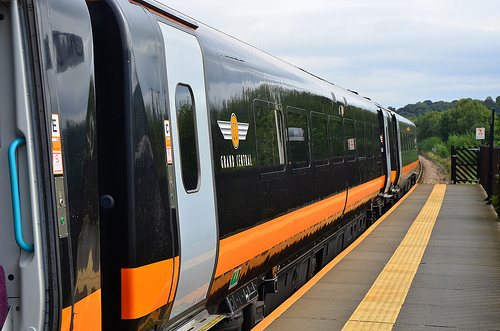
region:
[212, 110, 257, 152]
Orange circle with silver wings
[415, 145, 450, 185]
Dirt next to the train track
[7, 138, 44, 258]
Long blue door handle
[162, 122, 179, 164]
Sign next to the window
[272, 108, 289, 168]
Window on the side of the train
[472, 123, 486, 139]
White sign on the platform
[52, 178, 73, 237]
Silver and green buttons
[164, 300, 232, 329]
Silver step to the door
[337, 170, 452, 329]
Yellow stripe on the pavement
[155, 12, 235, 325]
Tall silver door of the train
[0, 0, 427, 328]
Train is sitting on tracks.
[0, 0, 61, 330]
Train door is open.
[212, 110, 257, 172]
Train logo is orange and white.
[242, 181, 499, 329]
Passenger loading area is concrete.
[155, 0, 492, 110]
Sky is lightly cloudy.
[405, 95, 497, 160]
Lush wooded area.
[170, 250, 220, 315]
Reflection from passenger loading area.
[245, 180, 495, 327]
Passenger loading area.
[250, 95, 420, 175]
Row of dark windows.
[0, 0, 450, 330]
Train has orange stripe.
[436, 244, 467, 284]
part of a floor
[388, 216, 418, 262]
part of a floor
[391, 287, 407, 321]
edge of a line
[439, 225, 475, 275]
part of a floor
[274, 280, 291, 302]
part of a wheel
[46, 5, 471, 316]
modern train at a station stop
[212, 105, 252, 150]
logo of the conveyance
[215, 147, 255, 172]
name of the train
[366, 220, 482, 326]
the station's platform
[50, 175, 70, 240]
door's red/green lights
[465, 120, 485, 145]
caution sign at end of platform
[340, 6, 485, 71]
cloudy sky above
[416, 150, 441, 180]
dirt road along the track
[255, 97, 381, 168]
row of seat windows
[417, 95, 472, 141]
wooded area in the distance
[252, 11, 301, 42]
white clouds in blue sky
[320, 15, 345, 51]
white clouds in blue sky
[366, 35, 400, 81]
white clouds in blue sky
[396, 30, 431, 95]
white clouds in blue sky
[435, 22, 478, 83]
white clouds in blue sky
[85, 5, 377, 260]
black and orange passenger train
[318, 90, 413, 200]
black and orange passenger train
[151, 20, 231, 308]
silver door in train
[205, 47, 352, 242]
passenger train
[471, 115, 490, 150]
red black and white sign